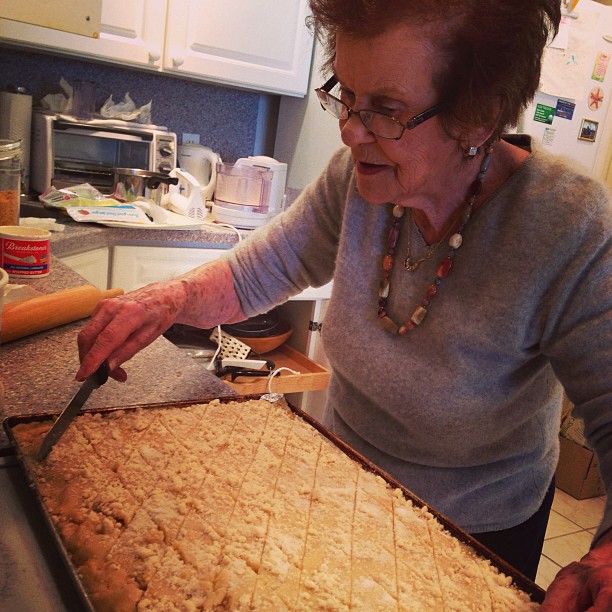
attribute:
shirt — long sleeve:
[234, 106, 610, 543]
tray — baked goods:
[3, 391, 570, 609]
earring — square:
[420, 96, 509, 176]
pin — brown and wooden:
[8, 247, 120, 352]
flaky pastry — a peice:
[296, 496, 376, 557]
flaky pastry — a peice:
[313, 519, 407, 596]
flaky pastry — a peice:
[337, 484, 409, 563]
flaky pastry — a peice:
[137, 427, 223, 510]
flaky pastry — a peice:
[124, 415, 187, 480]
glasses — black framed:
[307, 76, 446, 142]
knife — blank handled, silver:
[25, 361, 117, 464]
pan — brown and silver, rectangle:
[1, 387, 576, 609]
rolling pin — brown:
[0, 274, 132, 349]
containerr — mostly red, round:
[0, 211, 56, 283]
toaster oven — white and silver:
[30, 97, 198, 197]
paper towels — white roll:
[0, 74, 50, 219]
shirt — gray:
[211, 140, 609, 532]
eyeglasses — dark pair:
[286, 56, 486, 152]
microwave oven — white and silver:
[23, 107, 181, 207]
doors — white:
[171, 123, 244, 143]